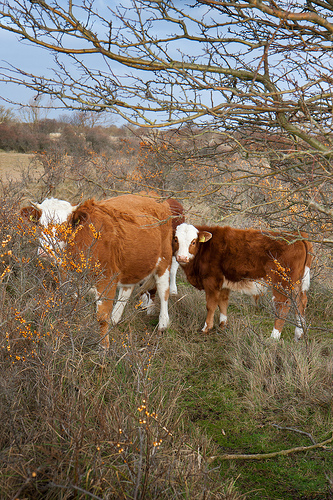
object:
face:
[36, 200, 70, 265]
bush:
[6, 114, 189, 188]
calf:
[172, 222, 313, 341]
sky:
[1, 0, 332, 135]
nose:
[177, 254, 187, 261]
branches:
[125, 9, 330, 62]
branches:
[205, 0, 333, 35]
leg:
[110, 282, 135, 325]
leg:
[153, 255, 172, 318]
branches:
[208, 434, 332, 461]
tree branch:
[0, 12, 98, 53]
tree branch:
[26, 0, 99, 47]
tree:
[0, 4, 331, 219]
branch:
[82, 2, 111, 53]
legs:
[95, 277, 116, 346]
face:
[173, 222, 198, 264]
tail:
[300, 233, 311, 293]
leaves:
[2, 208, 118, 339]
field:
[0, 128, 332, 500]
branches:
[1, 1, 333, 163]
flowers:
[132, 156, 176, 187]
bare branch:
[192, 134, 303, 199]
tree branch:
[197, 82, 325, 203]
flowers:
[23, 216, 105, 292]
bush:
[0, 216, 246, 500]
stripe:
[170, 219, 200, 260]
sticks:
[11, 330, 191, 485]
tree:
[9, 99, 185, 329]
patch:
[179, 372, 278, 457]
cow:
[19, 190, 173, 361]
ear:
[198, 231, 213, 243]